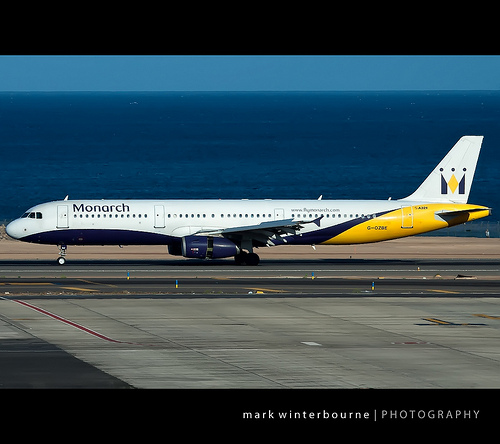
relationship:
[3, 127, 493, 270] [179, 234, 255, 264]
jet has left engine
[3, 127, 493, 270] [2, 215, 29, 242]
jet has nose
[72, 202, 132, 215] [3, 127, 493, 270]
monarch on side of jet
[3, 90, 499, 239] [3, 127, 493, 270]
water behind jet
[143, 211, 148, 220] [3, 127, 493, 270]
window on side of jet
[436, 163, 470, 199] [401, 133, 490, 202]
symbol on tail of plane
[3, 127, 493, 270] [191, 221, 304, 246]
jet has left wing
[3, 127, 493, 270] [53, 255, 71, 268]
jet has front wheel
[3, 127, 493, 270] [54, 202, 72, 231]
jet has door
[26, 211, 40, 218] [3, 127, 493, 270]
window on front of jet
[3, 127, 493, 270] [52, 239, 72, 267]
jet has front landing gear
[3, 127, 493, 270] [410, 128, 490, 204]
jet has tail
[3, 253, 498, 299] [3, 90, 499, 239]
runway by water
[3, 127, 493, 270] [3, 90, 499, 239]
jet next to water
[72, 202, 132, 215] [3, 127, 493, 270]
monarch written on jet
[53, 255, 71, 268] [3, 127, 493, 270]
front wheel on jet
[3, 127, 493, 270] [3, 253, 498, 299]
jet on top of runway